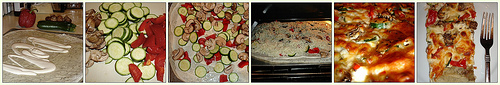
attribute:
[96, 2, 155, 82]
zuchinni — cut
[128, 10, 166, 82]
pepper — cut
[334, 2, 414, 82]
cheese — melted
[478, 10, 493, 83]
fork — silver